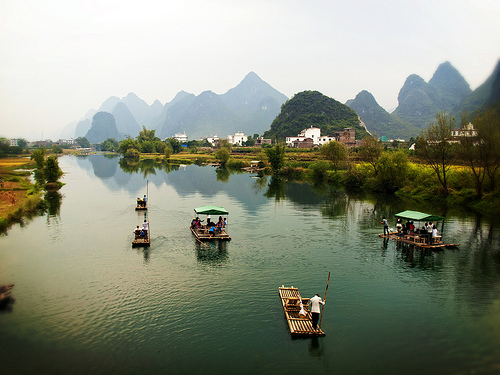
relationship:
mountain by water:
[173, 70, 283, 145] [57, 258, 174, 353]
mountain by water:
[220, 60, 295, 118] [50, 156, 223, 253]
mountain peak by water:
[395, 74, 440, 107] [49, 153, 496, 366]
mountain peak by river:
[427, 57, 485, 112] [0, 151, 499, 374]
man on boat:
[301, 290, 326, 335] [276, 284, 328, 339]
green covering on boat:
[190, 202, 232, 219] [187, 205, 232, 248]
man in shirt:
[379, 214, 389, 232] [380, 218, 390, 226]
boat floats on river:
[276, 277, 327, 342] [2, 151, 499, 373]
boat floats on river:
[373, 204, 461, 254] [2, 151, 499, 373]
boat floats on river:
[187, 195, 241, 250] [2, 151, 499, 373]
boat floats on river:
[135, 190, 149, 213] [2, 151, 499, 373]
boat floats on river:
[131, 217, 156, 249] [2, 151, 499, 373]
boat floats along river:
[130, 213, 152, 250] [2, 151, 499, 373]